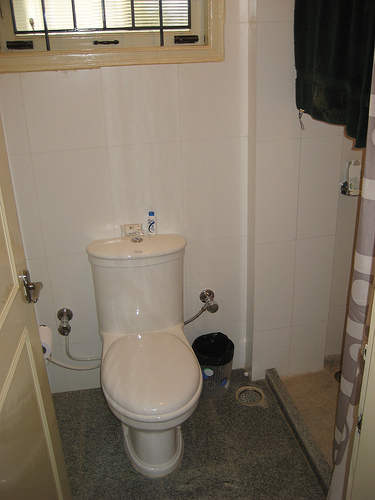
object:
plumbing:
[56, 307, 74, 336]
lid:
[100, 331, 200, 417]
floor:
[281, 372, 340, 468]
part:
[357, 200, 375, 297]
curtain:
[324, 39, 375, 500]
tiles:
[106, 141, 185, 239]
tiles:
[30, 146, 115, 257]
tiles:
[185, 235, 247, 326]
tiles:
[19, 67, 108, 155]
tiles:
[99, 62, 181, 149]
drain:
[236, 386, 270, 409]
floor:
[51, 367, 329, 500]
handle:
[18, 269, 45, 304]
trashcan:
[191, 331, 235, 396]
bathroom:
[0, 0, 375, 500]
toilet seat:
[102, 332, 204, 424]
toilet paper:
[38, 325, 53, 360]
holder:
[38, 323, 47, 355]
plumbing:
[199, 288, 219, 314]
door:
[0, 104, 74, 500]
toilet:
[84, 233, 204, 480]